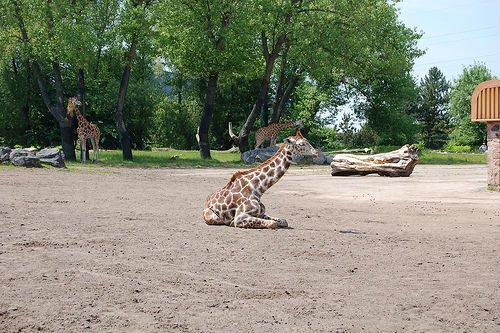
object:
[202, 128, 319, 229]
giraffe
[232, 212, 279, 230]
leg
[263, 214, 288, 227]
leg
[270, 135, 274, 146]
leg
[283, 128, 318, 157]
head